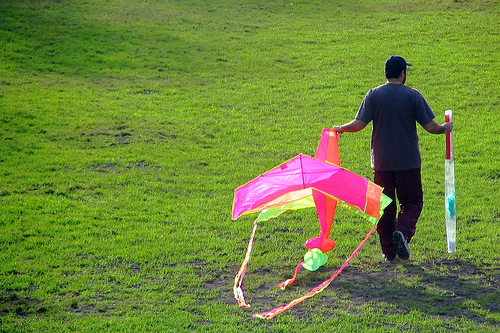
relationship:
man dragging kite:
[330, 55, 455, 266] [228, 125, 395, 325]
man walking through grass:
[330, 55, 455, 266] [1, 2, 499, 333]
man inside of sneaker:
[330, 55, 455, 266] [389, 225, 416, 264]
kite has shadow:
[228, 125, 395, 325] [257, 255, 499, 333]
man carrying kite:
[330, 55, 455, 266] [228, 125, 395, 325]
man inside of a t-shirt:
[330, 55, 455, 266] [355, 83, 436, 175]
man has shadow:
[330, 55, 455, 266] [257, 255, 499, 333]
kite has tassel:
[228, 125, 395, 325] [276, 262, 303, 294]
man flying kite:
[330, 55, 455, 266] [228, 125, 395, 325]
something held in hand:
[441, 106, 459, 256] [439, 120, 456, 138]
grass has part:
[1, 2, 499, 333] [79, 122, 146, 152]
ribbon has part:
[251, 223, 380, 324] [251, 305, 280, 321]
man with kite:
[330, 55, 455, 266] [228, 125, 395, 325]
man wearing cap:
[330, 55, 455, 266] [384, 54, 414, 70]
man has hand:
[330, 55, 455, 266] [439, 120, 456, 138]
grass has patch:
[1, 2, 499, 333] [88, 158, 139, 179]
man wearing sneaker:
[330, 55, 455, 266] [389, 225, 416, 264]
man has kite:
[330, 55, 455, 266] [228, 125, 395, 325]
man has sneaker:
[330, 55, 455, 266] [389, 225, 416, 264]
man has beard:
[330, 55, 455, 266] [401, 69, 408, 85]